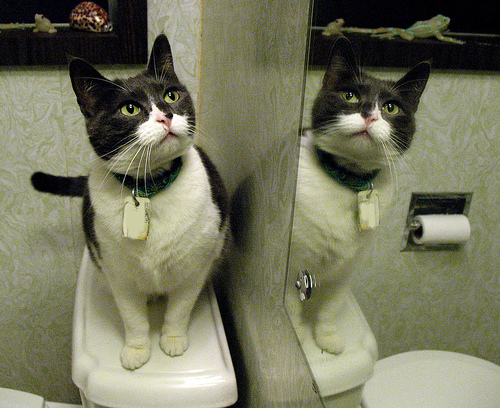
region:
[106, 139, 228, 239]
a cat with a collar on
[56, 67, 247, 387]
a cat sitting on a toilet lid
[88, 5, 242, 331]
a black and white cat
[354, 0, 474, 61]
a green frog with a blue stripe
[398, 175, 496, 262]
a roll of tissue in a bathroom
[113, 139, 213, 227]
a cat with a green collar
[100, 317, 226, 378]
a cat white paws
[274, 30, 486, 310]
a mirror in a bathroom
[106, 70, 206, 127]
a cat green eyes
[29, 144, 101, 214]
a cat black tail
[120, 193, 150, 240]
Tag on cat's collar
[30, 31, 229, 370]
Black and white cat on back of toilet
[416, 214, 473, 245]
White roll of toilet paper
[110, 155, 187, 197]
Collar around cat's neck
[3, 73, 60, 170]
Gold and white pattern on wallpaper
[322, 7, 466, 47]
Frog figurines reflected in mirror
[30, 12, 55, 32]
Frog figurine on window sill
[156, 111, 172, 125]
Black spot on cat's nose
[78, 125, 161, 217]
Whiskers on cat's face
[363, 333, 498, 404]
Toilet seat reflected in mirror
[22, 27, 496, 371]
a cat in a mirror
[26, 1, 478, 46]
this part of the picture has been altered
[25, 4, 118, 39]
a frog and a snail on a wire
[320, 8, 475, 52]
two frogs on a wire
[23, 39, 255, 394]
the cat is on a toilet lid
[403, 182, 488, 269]
this side of the picture has toilet paper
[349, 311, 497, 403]
the toilet lid is clearly seen on this side of the photo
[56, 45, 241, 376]
this is a two tone cat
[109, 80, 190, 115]
this cat has green eyes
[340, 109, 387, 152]
the cat has a two tone nose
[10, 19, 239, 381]
a cat white and black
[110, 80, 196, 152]
face of cat is black and white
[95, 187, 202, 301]
chest of cat is white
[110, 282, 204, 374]
front legs of cat are white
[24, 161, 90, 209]
a long black tail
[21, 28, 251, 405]
cat stands on white toilet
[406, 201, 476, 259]
a white paper toilet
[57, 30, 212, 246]
cat has a collar with a tag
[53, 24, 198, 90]
ears of cat are black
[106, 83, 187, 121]
eyes of cat are big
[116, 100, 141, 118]
beautiful green eyes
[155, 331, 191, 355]
white paws on cat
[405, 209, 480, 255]
roll of white toilet paper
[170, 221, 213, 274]
white fur on cat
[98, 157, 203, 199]
black collar around cat's neck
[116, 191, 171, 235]
name tag on silver chain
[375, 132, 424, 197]
tiny white whiskers on ca't face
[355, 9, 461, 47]
green lizard on wall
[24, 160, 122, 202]
long black tail on cat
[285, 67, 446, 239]
mirror on the wall